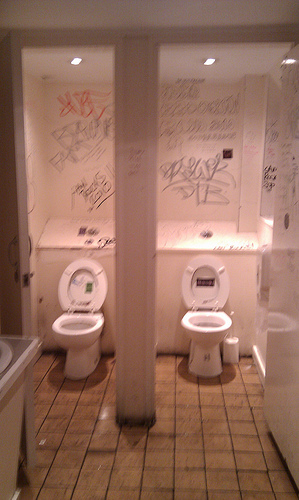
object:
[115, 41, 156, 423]
column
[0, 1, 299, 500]
bathroom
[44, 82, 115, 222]
wall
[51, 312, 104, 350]
bowl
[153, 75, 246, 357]
bathroom stall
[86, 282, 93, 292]
green patch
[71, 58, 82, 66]
lights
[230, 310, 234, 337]
toilet brush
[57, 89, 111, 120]
orange writing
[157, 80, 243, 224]
wall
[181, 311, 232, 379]
seat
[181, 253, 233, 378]
toilet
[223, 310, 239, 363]
bowl cleaner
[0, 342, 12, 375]
sink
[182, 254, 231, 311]
lid up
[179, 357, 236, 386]
shadow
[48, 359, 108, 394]
shadow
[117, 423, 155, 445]
shadow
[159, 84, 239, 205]
graffiti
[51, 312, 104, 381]
seat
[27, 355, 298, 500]
floor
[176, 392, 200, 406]
floor tile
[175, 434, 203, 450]
floor tile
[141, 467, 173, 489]
floor tile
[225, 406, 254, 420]
floor tile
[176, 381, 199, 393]
floor tile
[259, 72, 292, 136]
mirror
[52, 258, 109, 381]
toilet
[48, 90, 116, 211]
graffiti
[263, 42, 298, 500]
side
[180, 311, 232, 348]
toilet bowl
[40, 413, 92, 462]
part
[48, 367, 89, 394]
part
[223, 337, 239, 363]
part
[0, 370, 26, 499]
part